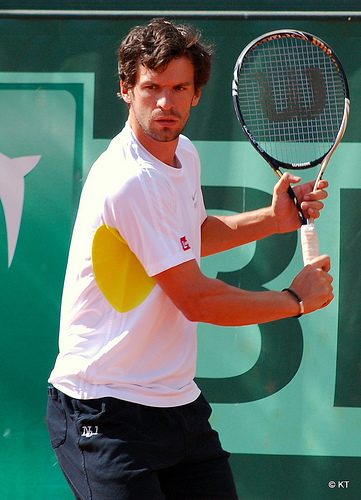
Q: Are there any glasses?
A: No, there are no glasses.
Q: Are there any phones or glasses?
A: No, there are no glasses or phones.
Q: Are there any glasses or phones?
A: No, there are no glasses or phones.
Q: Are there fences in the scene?
A: No, there are no fences.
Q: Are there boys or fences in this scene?
A: No, there are no fences or boys.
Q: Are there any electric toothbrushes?
A: No, there are no electric toothbrushes.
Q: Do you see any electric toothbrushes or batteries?
A: No, there are no electric toothbrushes or batteries.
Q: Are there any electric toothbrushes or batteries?
A: No, there are no electric toothbrushes or batteries.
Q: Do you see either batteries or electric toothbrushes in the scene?
A: No, there are no electric toothbrushes or batteries.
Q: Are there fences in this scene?
A: No, there are no fences.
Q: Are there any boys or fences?
A: No, there are no fences or boys.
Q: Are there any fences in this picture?
A: No, there are no fences.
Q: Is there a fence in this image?
A: No, there are no fences.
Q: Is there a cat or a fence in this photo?
A: No, there are no fences or cats.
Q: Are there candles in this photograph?
A: No, there are no candles.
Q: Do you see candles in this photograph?
A: No, there are no candles.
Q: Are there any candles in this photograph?
A: No, there are no candles.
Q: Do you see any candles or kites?
A: No, there are no candles or kites.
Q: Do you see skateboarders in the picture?
A: No, there are no skateboarders.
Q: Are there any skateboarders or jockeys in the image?
A: No, there are no skateboarders or jockeys.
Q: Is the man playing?
A: Yes, the man is playing.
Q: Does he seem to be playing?
A: Yes, the man is playing.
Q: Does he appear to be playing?
A: Yes, the man is playing.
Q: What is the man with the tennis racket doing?
A: The man is playing.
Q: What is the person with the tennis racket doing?
A: The man is playing.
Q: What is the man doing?
A: The man is playing.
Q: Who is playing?
A: The man is playing.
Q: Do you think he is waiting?
A: No, the man is playing.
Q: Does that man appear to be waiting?
A: No, the man is playing.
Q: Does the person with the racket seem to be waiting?
A: No, the man is playing.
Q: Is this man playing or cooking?
A: The man is playing.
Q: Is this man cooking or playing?
A: The man is playing.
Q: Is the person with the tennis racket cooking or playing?
A: The man is playing.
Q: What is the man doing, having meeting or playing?
A: The man is playing.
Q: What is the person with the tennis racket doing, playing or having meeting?
A: The man is playing.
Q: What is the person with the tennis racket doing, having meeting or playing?
A: The man is playing.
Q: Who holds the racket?
A: The man holds the racket.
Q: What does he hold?
A: The man holds the racket.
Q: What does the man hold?
A: The man holds the racket.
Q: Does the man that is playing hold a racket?
A: Yes, the man holds a racket.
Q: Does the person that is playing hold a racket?
A: Yes, the man holds a racket.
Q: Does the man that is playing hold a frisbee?
A: No, the man holds a racket.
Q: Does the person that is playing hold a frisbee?
A: No, the man holds a racket.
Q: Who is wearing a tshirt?
A: The man is wearing a tshirt.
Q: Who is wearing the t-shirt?
A: The man is wearing a tshirt.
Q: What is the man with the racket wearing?
A: The man is wearing a tee shirt.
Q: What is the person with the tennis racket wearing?
A: The man is wearing a tee shirt.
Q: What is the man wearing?
A: The man is wearing a tee shirt.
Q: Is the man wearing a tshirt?
A: Yes, the man is wearing a tshirt.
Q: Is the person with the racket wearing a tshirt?
A: Yes, the man is wearing a tshirt.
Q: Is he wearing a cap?
A: No, the man is wearing a tshirt.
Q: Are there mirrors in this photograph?
A: No, there are no mirrors.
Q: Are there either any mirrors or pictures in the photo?
A: No, there are no mirrors or pictures.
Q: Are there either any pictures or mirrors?
A: No, there are no mirrors or pictures.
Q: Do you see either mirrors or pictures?
A: No, there are no mirrors or pictures.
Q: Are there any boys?
A: No, there are no boys.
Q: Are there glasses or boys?
A: No, there are no boys or glasses.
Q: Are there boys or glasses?
A: No, there are no boys or glasses.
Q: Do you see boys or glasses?
A: No, there are no boys or glasses.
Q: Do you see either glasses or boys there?
A: No, there are no boys or glasses.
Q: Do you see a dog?
A: No, there are no dogs.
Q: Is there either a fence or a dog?
A: No, there are no dogs or fences.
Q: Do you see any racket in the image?
A: Yes, there is a racket.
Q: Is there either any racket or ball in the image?
A: Yes, there is a racket.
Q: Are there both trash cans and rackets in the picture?
A: No, there is a racket but no trash cans.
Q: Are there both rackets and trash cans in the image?
A: No, there is a racket but no trash cans.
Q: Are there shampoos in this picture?
A: No, there are no shampoos.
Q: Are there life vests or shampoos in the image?
A: No, there are no shampoos or life vests.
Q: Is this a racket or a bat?
A: This is a racket.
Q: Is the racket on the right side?
A: Yes, the racket is on the right of the image.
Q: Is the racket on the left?
A: No, the racket is on the right of the image.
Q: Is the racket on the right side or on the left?
A: The racket is on the right of the image.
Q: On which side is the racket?
A: The racket is on the right of the image.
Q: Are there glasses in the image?
A: No, there are no glasses.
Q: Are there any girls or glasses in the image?
A: No, there are no glasses or girls.